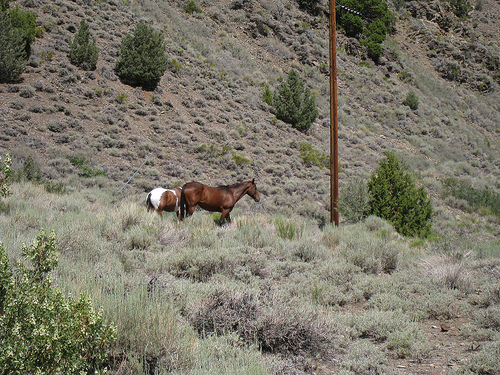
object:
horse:
[180, 178, 262, 224]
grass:
[1, 179, 500, 375]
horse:
[143, 186, 183, 224]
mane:
[213, 181, 246, 189]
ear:
[251, 178, 255, 184]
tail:
[179, 183, 188, 221]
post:
[326, 0, 345, 228]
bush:
[113, 19, 170, 92]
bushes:
[1, 0, 43, 84]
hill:
[3, 0, 499, 218]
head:
[246, 177, 259, 202]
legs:
[186, 206, 232, 226]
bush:
[186, 287, 346, 365]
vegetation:
[0, 0, 499, 375]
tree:
[365, 154, 435, 244]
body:
[179, 182, 241, 210]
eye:
[255, 187, 257, 190]